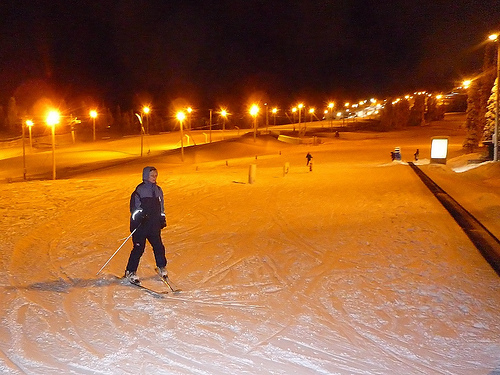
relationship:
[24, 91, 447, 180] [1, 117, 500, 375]
lights shine on slope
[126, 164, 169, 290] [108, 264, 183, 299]
woman on skis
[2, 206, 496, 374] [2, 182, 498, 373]
ski marks in snow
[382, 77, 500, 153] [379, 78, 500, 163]
snow on trees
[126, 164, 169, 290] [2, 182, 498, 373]
person in snow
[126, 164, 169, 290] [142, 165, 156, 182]
woman wearing hood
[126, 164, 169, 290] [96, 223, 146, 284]
woman holding ski pole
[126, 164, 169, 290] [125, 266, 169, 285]
woman has boots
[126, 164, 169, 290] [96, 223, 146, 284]
woman holds ski pole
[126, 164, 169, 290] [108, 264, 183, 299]
woman has skis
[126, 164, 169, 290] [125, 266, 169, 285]
woman has white boots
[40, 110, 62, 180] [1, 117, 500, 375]
light at end of slope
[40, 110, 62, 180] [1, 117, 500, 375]
light at top of slope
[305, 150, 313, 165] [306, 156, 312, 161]
person in dark jacket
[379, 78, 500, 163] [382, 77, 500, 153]
trees covered in snow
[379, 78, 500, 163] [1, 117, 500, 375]
trees lining slope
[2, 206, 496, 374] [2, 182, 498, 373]
tracks in snow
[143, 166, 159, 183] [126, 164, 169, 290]
head of woman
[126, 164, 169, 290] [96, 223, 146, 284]
person holding poles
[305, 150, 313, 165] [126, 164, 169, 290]
person behind woman